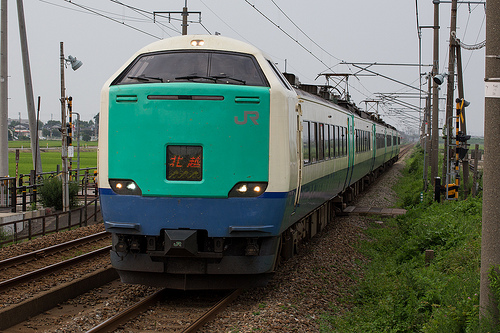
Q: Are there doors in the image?
A: Yes, there is a door.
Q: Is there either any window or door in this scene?
A: Yes, there is a door.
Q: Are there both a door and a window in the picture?
A: Yes, there are both a door and a window.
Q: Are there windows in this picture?
A: Yes, there are windows.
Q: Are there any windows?
A: Yes, there are windows.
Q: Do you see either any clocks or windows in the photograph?
A: Yes, there are windows.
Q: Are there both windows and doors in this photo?
A: Yes, there are both windows and a door.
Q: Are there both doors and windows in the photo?
A: Yes, there are both windows and a door.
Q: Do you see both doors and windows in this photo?
A: Yes, there are both windows and a door.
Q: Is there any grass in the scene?
A: Yes, there is grass.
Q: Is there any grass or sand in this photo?
A: Yes, there is grass.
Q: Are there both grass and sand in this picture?
A: No, there is grass but no sand.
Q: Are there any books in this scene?
A: No, there are no books.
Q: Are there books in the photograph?
A: No, there are no books.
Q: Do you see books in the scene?
A: No, there are no books.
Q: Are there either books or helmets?
A: No, there are no books or helmets.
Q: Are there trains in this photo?
A: Yes, there is a train.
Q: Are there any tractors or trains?
A: Yes, there is a train.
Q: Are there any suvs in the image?
A: No, there are no suvs.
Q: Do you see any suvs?
A: No, there are no suvs.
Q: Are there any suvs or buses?
A: No, there are no suvs or buses.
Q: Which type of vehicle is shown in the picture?
A: The vehicle is a train.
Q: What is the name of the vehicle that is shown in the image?
A: The vehicle is a train.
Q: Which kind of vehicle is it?
A: The vehicle is a train.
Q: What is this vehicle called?
A: This is a train.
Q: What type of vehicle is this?
A: This is a train.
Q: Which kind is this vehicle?
A: This is a train.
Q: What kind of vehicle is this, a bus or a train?
A: This is a train.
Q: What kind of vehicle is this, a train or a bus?
A: This is a train.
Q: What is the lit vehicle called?
A: The vehicle is a train.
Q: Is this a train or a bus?
A: This is a train.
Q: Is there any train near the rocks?
A: Yes, there is a train near the rocks.